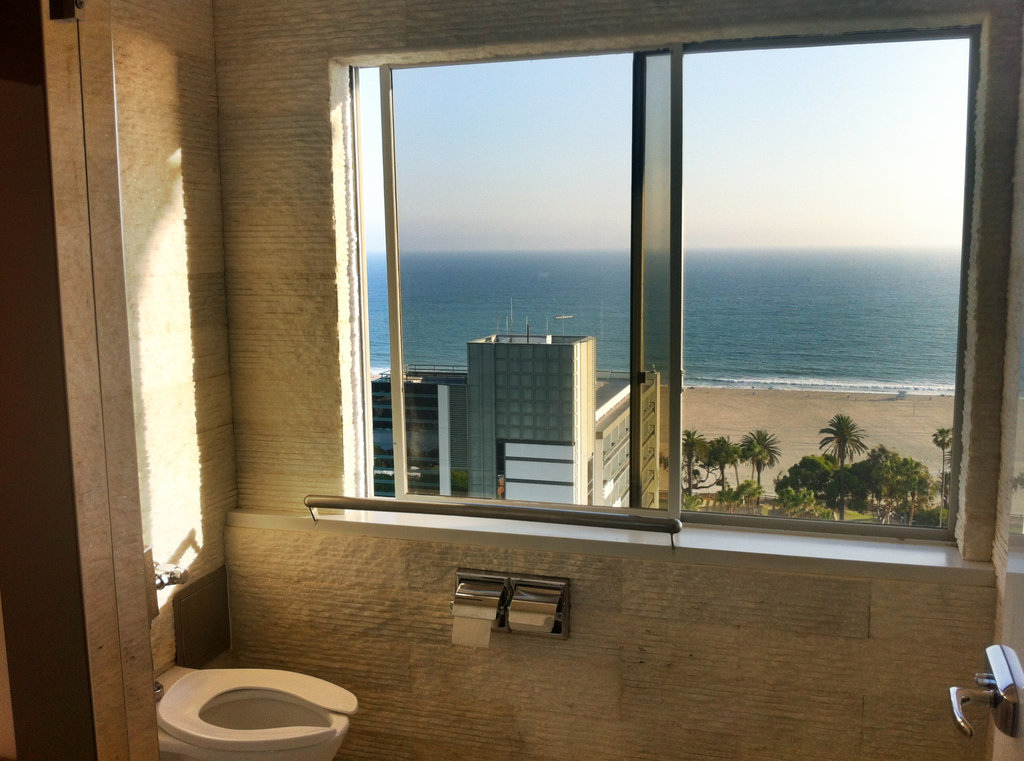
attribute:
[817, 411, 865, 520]
tree — green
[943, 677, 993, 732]
handle — metal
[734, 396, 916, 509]
trees — palm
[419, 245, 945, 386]
water — stretching, distant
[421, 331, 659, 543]
building — large, grey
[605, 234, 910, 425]
ocean — blue, nice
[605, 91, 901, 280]
sky — blue, cloudless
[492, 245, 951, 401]
ocean — huge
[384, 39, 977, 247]
sky — blue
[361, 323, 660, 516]
building — grey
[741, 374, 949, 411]
foam — white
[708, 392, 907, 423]
sand — brown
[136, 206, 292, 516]
ray — sunshine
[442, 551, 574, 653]
holder —  toilet paper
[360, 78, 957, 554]
window — large, open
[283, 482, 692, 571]
rail — Chrome hand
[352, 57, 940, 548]
sill — long brown window 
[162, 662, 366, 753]
toilet — white, porecelain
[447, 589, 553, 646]
rolls — toilet, paper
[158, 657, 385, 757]
seat — white